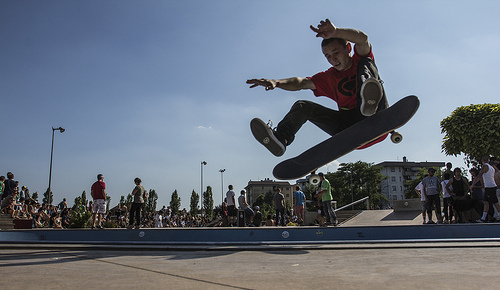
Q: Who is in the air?
A: Skater.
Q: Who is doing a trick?
A: Skater.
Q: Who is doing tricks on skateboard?
A: Young man is doing tricks.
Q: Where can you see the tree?
A: You can see it behind skateboarder.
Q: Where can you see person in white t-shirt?
A: In front of the tree on right.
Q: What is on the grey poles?
A: Lights are on the pole.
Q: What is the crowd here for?
A: To see skateboarder.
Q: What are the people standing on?
A: They are on cement.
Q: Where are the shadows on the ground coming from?
A: Shadows coming from trees.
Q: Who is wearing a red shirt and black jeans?
A: Skateboarder.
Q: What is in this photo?
A: A man on a skateboard doing a trick.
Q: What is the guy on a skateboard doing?
A: A trick.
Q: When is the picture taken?
A: Daytime.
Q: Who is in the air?
A: The boy.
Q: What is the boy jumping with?
A: A skate board.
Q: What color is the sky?
A: Blue.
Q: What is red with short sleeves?
A: The shirts.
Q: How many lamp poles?
A: Three.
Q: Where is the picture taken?
A: At a skateboard park in a city.